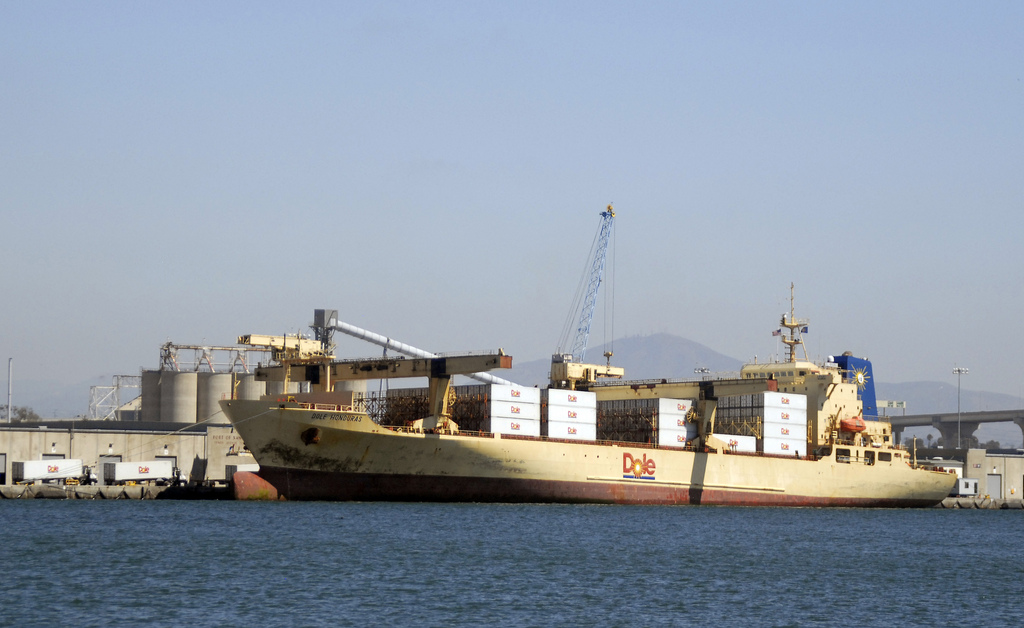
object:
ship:
[217, 383, 956, 506]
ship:
[217, 280, 957, 506]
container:
[764, 391, 808, 408]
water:
[0, 499, 1022, 622]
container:
[718, 391, 806, 408]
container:
[492, 384, 541, 405]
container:
[214, 371, 958, 505]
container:
[548, 389, 597, 409]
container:
[219, 284, 956, 506]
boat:
[221, 281, 961, 503]